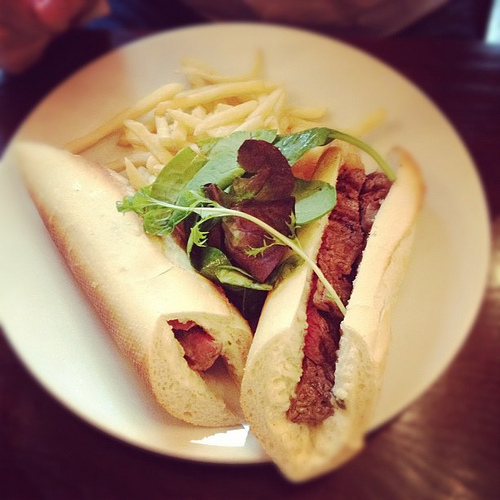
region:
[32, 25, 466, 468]
sandwich and french fries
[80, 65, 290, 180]
skinny yellow french fries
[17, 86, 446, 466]
white round plate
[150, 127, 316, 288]
green and purple lettuce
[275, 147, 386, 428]
brown meat in sandwich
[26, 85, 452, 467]
meal for lunch or dinner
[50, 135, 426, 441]
sandwich cut in two pieces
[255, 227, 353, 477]
white roll bread split in center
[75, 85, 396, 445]
sandwich, salad and french fries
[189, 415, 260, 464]
light reflecting on plate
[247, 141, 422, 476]
bread is tan and fluffy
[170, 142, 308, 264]
Lettuce garnish on food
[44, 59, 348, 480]
A plate with food on it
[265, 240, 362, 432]
Minced meat on bun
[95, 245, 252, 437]
Hot dog on a bun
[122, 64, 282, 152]
French fries on plate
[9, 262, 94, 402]
White plate on table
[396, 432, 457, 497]
brown colored wooden table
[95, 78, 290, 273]
Fries and lettuce on a plate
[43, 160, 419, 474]
Two buns with meat and lettuce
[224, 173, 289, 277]
Purple lettuce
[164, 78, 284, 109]
golden thin french fry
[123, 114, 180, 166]
golden thin french fry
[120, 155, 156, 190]
golden thin french fry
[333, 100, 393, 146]
golden thin french fry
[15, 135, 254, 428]
round french bread roll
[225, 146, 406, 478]
round french bread roll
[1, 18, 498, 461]
round ceramic white plate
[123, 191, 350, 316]
piece of green lettuce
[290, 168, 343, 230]
piece of green lettuce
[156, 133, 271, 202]
piece of green lettuce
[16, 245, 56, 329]
this is a plate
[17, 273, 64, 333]
the plate is white in color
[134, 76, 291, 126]
these are some French fries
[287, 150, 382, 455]
this is a hotdog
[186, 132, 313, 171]
this is a leaf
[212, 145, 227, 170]
the leaf is green in color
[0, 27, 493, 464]
the plate is round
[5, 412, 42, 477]
this is a table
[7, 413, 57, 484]
the table is wooden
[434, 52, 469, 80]
the table is brown in color